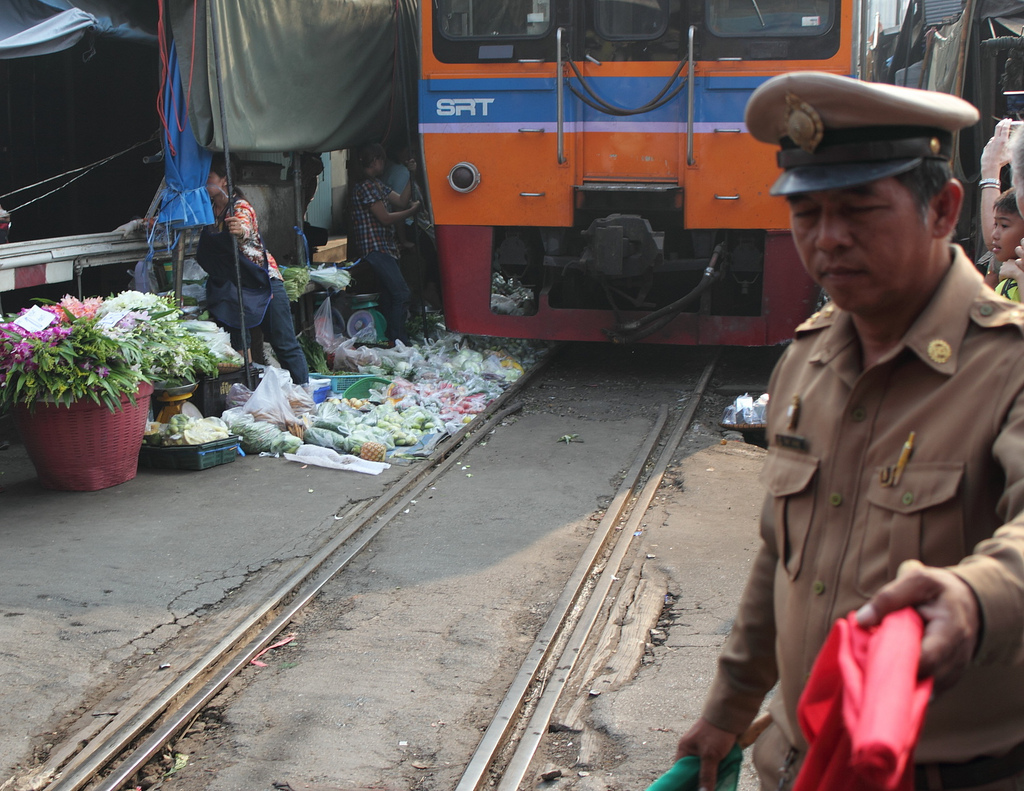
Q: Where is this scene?
A: On the train tracks.